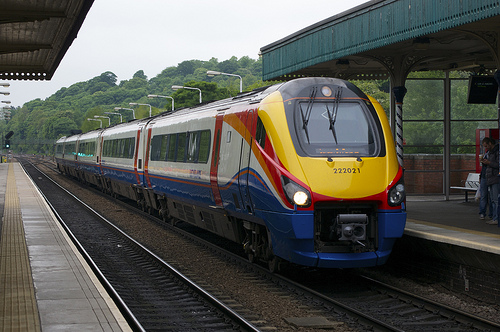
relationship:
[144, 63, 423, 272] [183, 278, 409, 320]
train on tracks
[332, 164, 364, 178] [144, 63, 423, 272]
numbers on front of train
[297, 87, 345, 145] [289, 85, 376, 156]
wipers on windshield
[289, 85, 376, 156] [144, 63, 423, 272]
windshield on front of train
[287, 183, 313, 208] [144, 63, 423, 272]
headlight on front of train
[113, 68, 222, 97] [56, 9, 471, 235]
lights at station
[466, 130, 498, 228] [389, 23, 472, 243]
passengers at train stop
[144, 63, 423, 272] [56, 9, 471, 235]
train at a station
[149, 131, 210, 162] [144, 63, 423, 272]
windows on side of train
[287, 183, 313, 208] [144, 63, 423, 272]
headlight of a train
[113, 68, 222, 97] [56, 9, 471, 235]
lights at a station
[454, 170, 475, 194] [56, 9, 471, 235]
bench at station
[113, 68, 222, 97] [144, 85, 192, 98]
lights in a row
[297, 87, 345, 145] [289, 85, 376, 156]
wipers on top of windshield